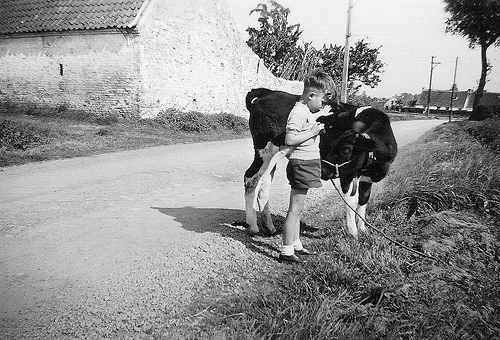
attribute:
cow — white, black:
[239, 86, 404, 253]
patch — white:
[347, 101, 380, 117]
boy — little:
[266, 55, 361, 282]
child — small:
[273, 62, 343, 269]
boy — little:
[277, 68, 335, 265]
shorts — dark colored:
[286, 154, 325, 189]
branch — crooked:
[467, 37, 492, 117]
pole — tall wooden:
[422, 52, 437, 117]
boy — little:
[258, 64, 350, 275]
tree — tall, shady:
[314, 40, 385, 101]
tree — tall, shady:
[244, 1, 304, 78]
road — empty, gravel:
[25, 169, 202, 294]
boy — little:
[282, 71, 337, 261]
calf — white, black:
[238, 83, 402, 250]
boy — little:
[166, 15, 389, 217]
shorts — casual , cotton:
[284, 154, 329, 193]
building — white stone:
[31, 2, 291, 154]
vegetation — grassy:
[244, 113, 497, 339]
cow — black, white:
[233, 82, 402, 247]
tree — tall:
[251, 0, 310, 96]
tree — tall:
[305, 41, 377, 98]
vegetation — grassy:
[268, 115, 499, 337]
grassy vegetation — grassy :
[255, 116, 497, 338]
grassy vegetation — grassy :
[2, 94, 250, 166]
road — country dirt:
[2, 117, 449, 338]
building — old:
[6, 6, 235, 111]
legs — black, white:
[235, 158, 277, 257]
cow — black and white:
[226, 77, 412, 255]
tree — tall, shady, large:
[444, 1, 498, 106]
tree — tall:
[441, 0, 484, 118]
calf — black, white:
[241, 87, 398, 241]